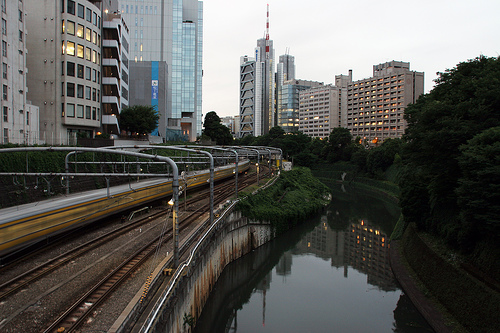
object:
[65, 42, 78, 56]
window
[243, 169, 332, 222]
vegetation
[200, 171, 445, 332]
river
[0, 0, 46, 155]
building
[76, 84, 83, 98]
window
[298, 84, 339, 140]
building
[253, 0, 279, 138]
building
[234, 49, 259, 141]
building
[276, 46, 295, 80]
building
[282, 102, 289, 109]
window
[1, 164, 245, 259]
train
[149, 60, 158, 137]
banner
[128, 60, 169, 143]
building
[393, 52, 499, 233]
trees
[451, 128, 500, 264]
bushes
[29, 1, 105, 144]
building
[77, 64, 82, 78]
window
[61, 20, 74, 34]
lights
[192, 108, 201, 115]
windows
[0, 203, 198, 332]
train tracks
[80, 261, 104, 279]
gravel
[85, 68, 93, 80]
window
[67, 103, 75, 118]
window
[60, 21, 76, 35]
window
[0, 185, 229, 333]
tracks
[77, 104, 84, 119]
window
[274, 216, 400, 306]
reflection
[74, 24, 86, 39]
window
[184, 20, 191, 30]
window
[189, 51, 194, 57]
window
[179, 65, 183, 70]
window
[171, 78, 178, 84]
window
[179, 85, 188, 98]
window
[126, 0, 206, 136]
building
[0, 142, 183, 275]
overhang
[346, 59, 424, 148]
building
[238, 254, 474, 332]
water